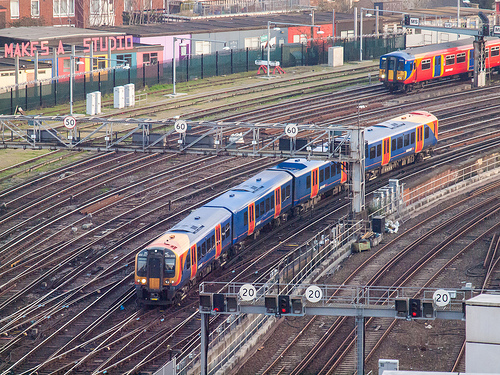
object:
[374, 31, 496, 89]
trains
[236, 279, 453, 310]
signs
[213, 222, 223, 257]
doors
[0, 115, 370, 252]
frame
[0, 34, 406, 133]
fence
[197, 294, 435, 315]
lights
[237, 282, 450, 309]
speed limit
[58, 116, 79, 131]
speed limit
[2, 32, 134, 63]
sign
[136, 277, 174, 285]
headlights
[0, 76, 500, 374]
track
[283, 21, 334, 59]
building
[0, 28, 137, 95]
building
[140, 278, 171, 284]
headlight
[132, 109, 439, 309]
car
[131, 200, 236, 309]
engine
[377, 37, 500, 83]
engine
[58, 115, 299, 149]
signal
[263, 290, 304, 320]
signal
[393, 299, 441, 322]
signal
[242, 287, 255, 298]
sign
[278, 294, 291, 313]
light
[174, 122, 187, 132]
number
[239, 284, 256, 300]
20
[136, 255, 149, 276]
windshield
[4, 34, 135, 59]
letters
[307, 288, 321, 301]
sign